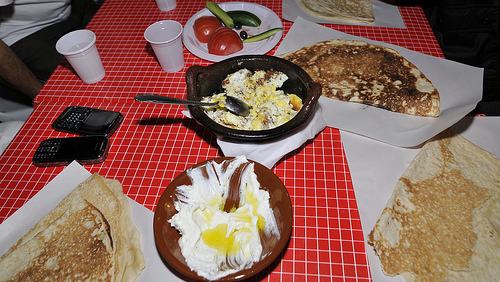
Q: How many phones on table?
A: Two.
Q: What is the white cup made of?
A: Plastic.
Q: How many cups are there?
A: Three.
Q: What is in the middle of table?
A: Eggs.